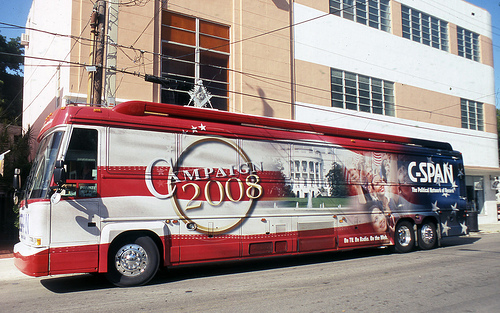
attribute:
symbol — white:
[175, 75, 221, 108]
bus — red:
[44, 82, 498, 264]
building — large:
[14, 9, 494, 194]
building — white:
[21, 5, 497, 222]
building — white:
[274, 1, 496, 201]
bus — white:
[334, 139, 435, 204]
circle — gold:
[152, 132, 278, 235]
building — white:
[280, 5, 487, 134]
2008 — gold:
[174, 171, 274, 216]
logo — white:
[369, 134, 494, 189]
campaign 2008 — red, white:
[142, 136, 262, 237]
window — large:
[328, 64, 399, 119]